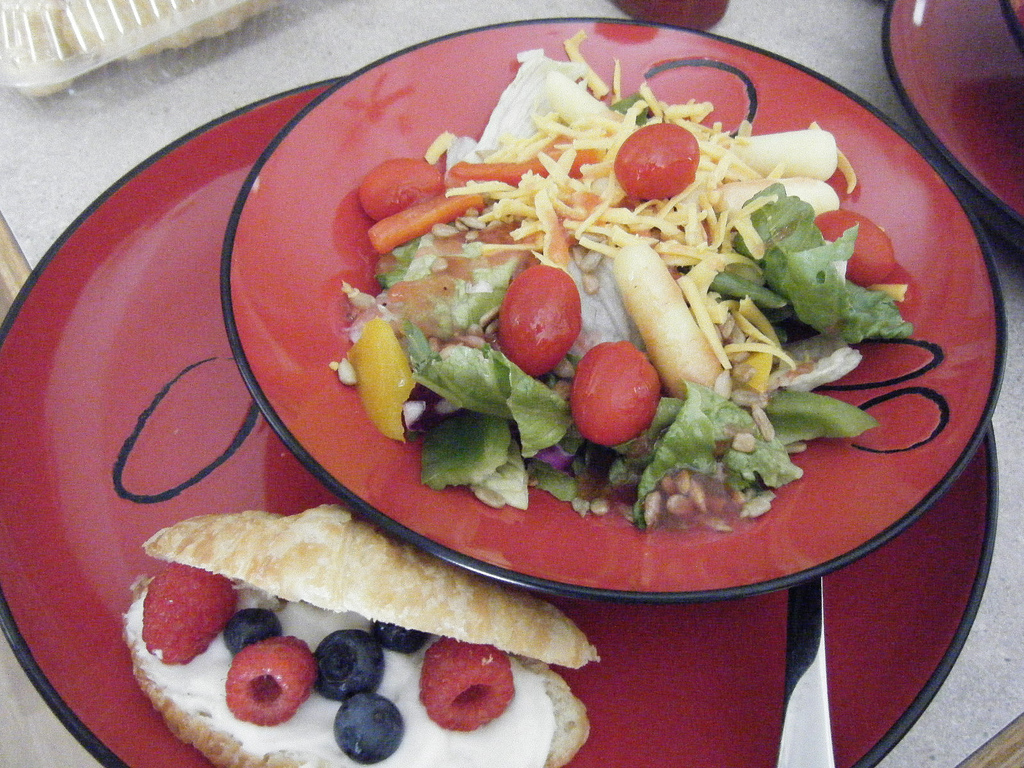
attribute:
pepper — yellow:
[340, 320, 429, 459]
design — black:
[55, 312, 284, 531]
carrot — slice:
[355, 167, 515, 263]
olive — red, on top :
[567, 327, 665, 461]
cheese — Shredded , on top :
[500, 148, 615, 224]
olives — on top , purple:
[318, 638, 409, 762]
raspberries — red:
[424, 638, 522, 740]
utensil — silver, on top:
[754, 601, 828, 755]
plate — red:
[27, 111, 980, 747]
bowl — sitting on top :
[253, 40, 973, 607]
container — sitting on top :
[14, 11, 211, 100]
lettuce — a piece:
[457, 48, 594, 174]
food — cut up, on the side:
[335, 262, 439, 464]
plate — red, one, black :
[199, 20, 992, 606]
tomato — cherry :
[610, 106, 697, 208]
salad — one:
[331, 35, 900, 509]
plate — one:
[212, 11, 932, 619]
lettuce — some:
[398, 318, 524, 513]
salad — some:
[340, 89, 876, 541]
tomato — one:
[560, 340, 671, 440]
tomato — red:
[605, 106, 711, 202]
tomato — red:
[794, 178, 909, 280]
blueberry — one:
[348, 681, 401, 764]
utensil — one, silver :
[750, 564, 872, 765]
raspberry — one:
[145, 553, 225, 675]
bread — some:
[100, 459, 615, 749]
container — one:
[5, 1, 291, 105]